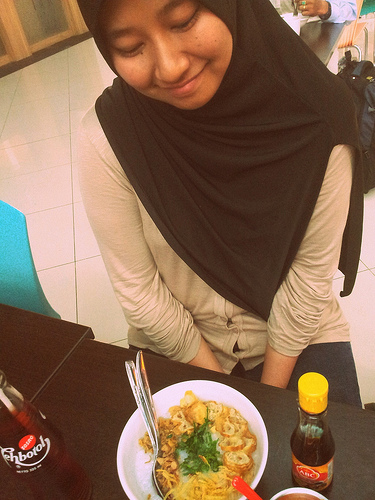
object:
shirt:
[82, 94, 356, 361]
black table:
[0, 309, 375, 498]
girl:
[72, 1, 365, 395]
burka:
[75, 0, 367, 320]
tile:
[348, 292, 372, 333]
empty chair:
[0, 201, 65, 316]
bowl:
[112, 374, 272, 500]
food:
[137, 390, 257, 498]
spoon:
[125, 345, 167, 500]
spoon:
[289, 0, 303, 22]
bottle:
[287, 367, 345, 495]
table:
[0, 303, 93, 497]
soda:
[0, 361, 67, 499]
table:
[287, 13, 346, 72]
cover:
[294, 371, 334, 419]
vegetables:
[157, 410, 241, 496]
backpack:
[335, 57, 375, 197]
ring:
[302, 3, 307, 10]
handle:
[351, 58, 372, 78]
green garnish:
[172, 414, 221, 480]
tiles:
[3, 130, 71, 184]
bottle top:
[292, 365, 333, 403]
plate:
[267, 482, 333, 500]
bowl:
[274, 7, 321, 46]